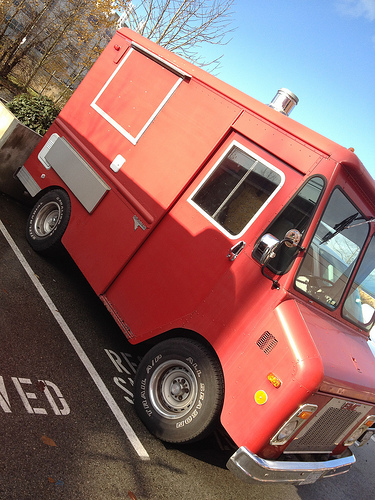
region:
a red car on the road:
[12, 23, 373, 480]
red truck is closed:
[16, 9, 373, 491]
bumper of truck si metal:
[218, 450, 362, 486]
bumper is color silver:
[220, 444, 362, 494]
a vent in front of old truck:
[287, 393, 368, 464]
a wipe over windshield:
[308, 181, 373, 268]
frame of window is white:
[176, 130, 294, 251]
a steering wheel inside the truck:
[297, 264, 345, 306]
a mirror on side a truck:
[273, 219, 309, 264]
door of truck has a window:
[106, 125, 301, 333]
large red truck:
[13, 7, 362, 476]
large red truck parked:
[10, 12, 361, 481]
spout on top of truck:
[261, 85, 304, 118]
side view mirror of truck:
[258, 233, 304, 272]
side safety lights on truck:
[248, 368, 284, 411]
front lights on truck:
[272, 399, 317, 468]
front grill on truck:
[276, 403, 372, 461]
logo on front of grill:
[336, 396, 363, 415]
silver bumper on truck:
[213, 444, 361, 494]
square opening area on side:
[72, 46, 193, 145]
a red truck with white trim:
[30, 15, 372, 310]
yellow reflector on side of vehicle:
[236, 368, 281, 416]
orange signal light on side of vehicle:
[252, 363, 294, 393]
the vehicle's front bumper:
[214, 431, 353, 494]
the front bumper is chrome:
[202, 440, 373, 491]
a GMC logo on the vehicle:
[310, 380, 372, 435]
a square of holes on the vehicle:
[260, 317, 283, 368]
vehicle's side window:
[100, 140, 294, 249]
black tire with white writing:
[15, 160, 112, 270]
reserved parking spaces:
[26, 292, 148, 487]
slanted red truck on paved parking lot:
[16, 19, 365, 484]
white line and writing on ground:
[0, 210, 140, 465]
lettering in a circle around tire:
[129, 330, 212, 436]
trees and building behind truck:
[1, 0, 226, 129]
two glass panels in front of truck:
[289, 180, 367, 330]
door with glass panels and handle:
[95, 120, 305, 355]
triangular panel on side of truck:
[245, 167, 324, 287]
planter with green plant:
[0, 86, 60, 169]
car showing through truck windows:
[281, 192, 371, 333]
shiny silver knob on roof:
[265, 83, 298, 114]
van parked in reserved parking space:
[9, 31, 372, 493]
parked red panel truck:
[29, 38, 374, 496]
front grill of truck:
[225, 382, 367, 483]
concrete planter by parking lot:
[0, 84, 62, 177]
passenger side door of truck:
[90, 120, 291, 360]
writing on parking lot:
[0, 331, 167, 432]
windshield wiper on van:
[320, 210, 369, 243]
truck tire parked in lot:
[125, 322, 226, 456]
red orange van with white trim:
[34, 43, 290, 283]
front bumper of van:
[222, 440, 366, 487]